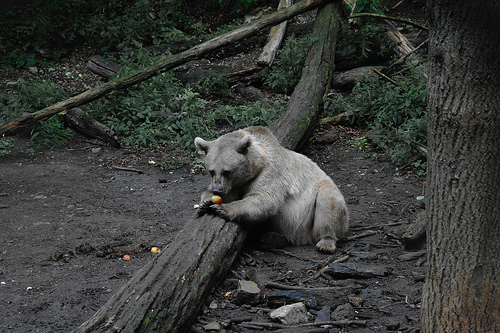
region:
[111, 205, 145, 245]
part of a ground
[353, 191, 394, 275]
part of a ground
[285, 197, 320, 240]
part of a tummy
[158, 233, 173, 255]
part of a ground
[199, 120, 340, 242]
this is a bear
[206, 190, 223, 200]
this is a fruit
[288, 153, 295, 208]
the bear is white in color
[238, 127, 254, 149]
this is the ear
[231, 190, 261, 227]
this is the leg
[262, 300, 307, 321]
this is a rock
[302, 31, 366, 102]
this is a tree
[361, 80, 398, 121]
the leaves are green in color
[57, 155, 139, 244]
this is the ground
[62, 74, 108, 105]
this is a dry wood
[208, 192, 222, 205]
A red and green apple.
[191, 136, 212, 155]
A grey right ear of a bear.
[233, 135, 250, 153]
A grey left ear of a bear.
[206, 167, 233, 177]
Two front black eyes on a bears face.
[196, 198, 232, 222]
Giant bear paws with claws on them.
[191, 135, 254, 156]
Two large bear ears on a bear head.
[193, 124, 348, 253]
A large grey and tan bear leaning on a log eating an apple.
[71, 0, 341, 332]
A long tree trunk a bear is leaning on.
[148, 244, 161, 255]
Green and red apple next to a log.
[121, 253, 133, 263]
Smaller red apple on the ground.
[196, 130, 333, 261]
the dog is eating afruit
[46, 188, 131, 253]
the floor is dirty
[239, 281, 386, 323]
pieces of tree log are scatered on the ground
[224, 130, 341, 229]
the dog is light brown in color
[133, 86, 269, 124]
the plants are green in color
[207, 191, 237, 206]
the fruit is orange in color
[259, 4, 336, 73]
the logs are wooden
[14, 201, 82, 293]
the floor is black in color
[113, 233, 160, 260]
the fruits are fallen on the floor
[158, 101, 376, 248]
bear in the photo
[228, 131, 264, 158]
ear of the bear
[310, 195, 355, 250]
leg of the bear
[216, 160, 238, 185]
eye of the bear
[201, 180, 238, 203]
nose of the bear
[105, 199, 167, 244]
ground next to bear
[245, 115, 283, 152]
back of the bear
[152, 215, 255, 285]
log in front of bear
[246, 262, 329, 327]
stuff next to bear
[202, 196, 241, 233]
paw of the bear